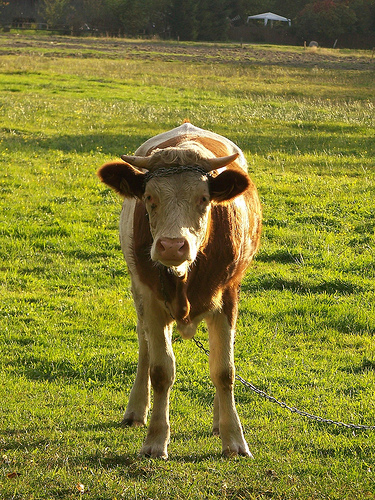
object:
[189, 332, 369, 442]
chain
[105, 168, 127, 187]
fur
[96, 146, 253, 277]
head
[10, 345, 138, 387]
shadow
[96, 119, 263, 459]
cow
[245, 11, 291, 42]
tent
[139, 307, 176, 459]
front leg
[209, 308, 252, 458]
front leg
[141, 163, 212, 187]
chain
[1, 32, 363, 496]
grass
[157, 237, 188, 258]
nose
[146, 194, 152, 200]
eye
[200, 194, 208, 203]
eye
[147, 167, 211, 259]
face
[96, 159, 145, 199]
ear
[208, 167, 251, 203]
ear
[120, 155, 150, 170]
horn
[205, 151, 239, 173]
horn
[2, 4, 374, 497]
area